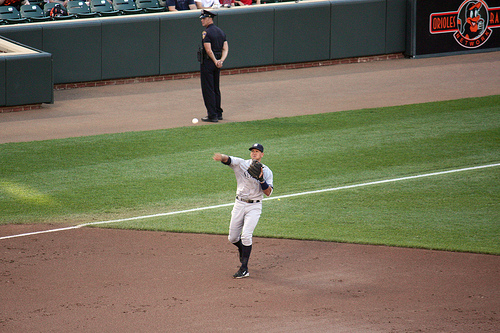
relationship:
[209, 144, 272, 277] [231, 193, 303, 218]
man has belt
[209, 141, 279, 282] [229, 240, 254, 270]
man has socks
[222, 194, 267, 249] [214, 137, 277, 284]
pants on man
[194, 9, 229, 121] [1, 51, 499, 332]
man in ground